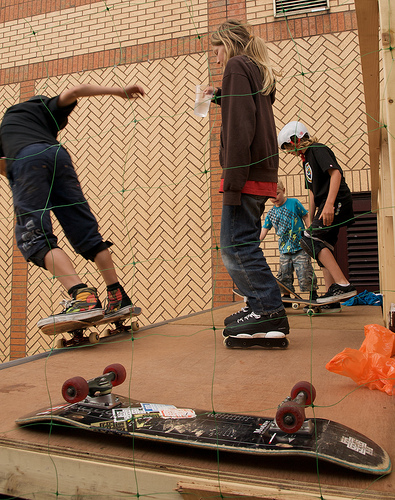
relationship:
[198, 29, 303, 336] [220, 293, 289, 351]
girl wearing skates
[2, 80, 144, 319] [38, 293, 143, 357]
boy on skateboard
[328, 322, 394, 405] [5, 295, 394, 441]
paper on ground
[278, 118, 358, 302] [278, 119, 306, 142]
boy wears helmet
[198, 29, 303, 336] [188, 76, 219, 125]
girl holds cup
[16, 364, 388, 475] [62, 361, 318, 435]
skateboard has wheels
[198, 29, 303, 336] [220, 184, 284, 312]
girl wears jeans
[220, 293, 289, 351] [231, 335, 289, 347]
skates have wheels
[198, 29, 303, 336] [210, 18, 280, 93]
girl has ponytail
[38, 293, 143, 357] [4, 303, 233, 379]
skateboard near ramp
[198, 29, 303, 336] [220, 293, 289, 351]
girl wears skates